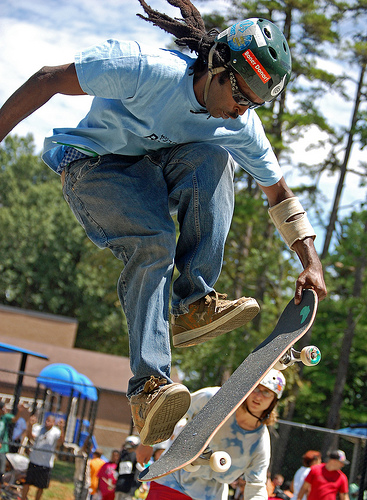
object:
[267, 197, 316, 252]
band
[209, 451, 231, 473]
wheels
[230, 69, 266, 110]
glasses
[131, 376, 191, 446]
sneakers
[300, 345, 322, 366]
wheel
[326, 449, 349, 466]
baseball cap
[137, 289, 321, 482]
skateboard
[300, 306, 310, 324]
country